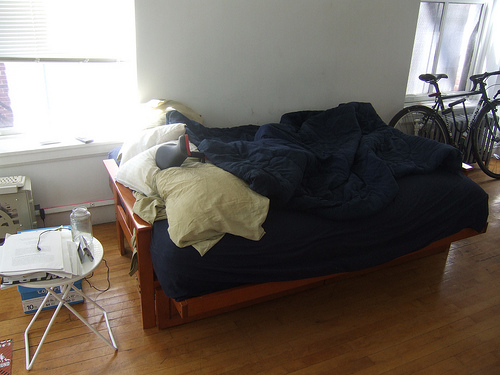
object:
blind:
[0, 0, 137, 64]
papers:
[0, 230, 84, 279]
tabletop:
[0, 227, 104, 288]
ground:
[437, 172, 484, 208]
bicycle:
[388, 70, 499, 180]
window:
[0, 0, 133, 135]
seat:
[418, 73, 449, 84]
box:
[15, 225, 85, 315]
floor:
[161, 332, 500, 375]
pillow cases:
[115, 138, 201, 198]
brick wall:
[170, 35, 351, 88]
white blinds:
[0, 0, 125, 63]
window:
[403, 0, 488, 97]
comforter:
[111, 100, 462, 258]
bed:
[102, 149, 490, 331]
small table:
[1, 230, 119, 371]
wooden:
[367, 324, 419, 370]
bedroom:
[0, 0, 500, 375]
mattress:
[107, 148, 490, 304]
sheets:
[107, 147, 489, 304]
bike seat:
[154, 134, 206, 170]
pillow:
[153, 156, 270, 250]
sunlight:
[67, 71, 137, 133]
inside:
[390, 74, 499, 216]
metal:
[22, 282, 118, 373]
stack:
[0, 204, 120, 372]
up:
[55, 66, 116, 146]